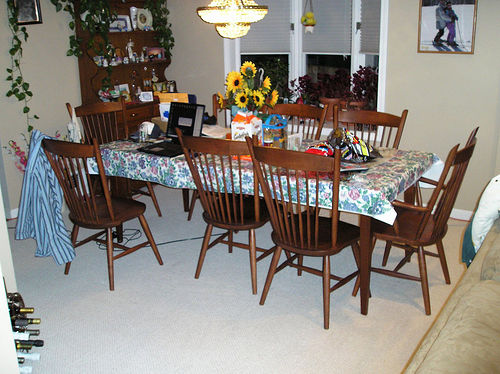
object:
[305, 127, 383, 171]
bags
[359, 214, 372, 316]
leg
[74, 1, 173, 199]
bookcase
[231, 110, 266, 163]
goldfish carton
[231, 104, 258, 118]
basket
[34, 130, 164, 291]
chair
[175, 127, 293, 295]
chairs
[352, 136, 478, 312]
chairs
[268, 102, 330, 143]
chairs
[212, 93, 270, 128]
chairs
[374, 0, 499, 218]
wall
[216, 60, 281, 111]
daisies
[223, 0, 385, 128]
window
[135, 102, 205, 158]
laptop computer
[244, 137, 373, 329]
chair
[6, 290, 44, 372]
bottles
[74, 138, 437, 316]
table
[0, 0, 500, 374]
dining room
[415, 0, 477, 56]
people photo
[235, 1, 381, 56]
blinds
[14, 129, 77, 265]
shirt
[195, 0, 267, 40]
light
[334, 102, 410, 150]
chairs